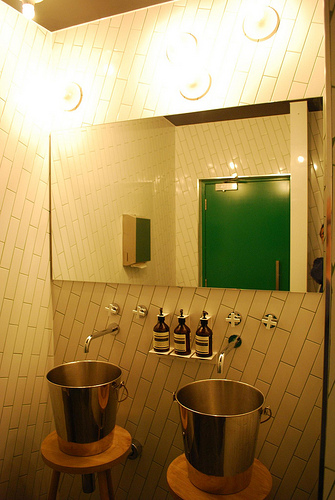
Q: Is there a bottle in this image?
A: Yes, there is a bottle.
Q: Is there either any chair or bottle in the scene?
A: Yes, there is a bottle.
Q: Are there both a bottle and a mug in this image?
A: No, there is a bottle but no mugs.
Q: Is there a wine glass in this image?
A: No, there are no wine glasses.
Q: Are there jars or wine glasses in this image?
A: No, there are no wine glasses or jars.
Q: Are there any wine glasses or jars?
A: No, there are no wine glasses or jars.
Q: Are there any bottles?
A: Yes, there is a bottle.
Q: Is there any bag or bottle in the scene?
A: Yes, there is a bottle.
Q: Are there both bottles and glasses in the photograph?
A: No, there is a bottle but no glasses.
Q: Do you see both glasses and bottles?
A: No, there is a bottle but no glasses.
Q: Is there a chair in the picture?
A: No, there are no chairs.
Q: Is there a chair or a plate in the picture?
A: No, there are no chairs or plates.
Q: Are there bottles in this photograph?
A: Yes, there is a bottle.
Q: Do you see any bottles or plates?
A: Yes, there is a bottle.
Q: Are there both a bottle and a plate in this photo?
A: No, there is a bottle but no plates.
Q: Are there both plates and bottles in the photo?
A: No, there is a bottle but no plates.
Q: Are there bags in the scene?
A: No, there are no bags.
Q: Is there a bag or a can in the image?
A: No, there are no bags or cans.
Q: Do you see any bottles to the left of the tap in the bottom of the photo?
A: Yes, there is a bottle to the left of the faucet.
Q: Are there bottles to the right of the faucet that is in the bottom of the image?
A: No, the bottle is to the left of the tap.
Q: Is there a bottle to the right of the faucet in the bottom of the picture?
A: No, the bottle is to the left of the tap.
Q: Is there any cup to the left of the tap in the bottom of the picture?
A: No, there is a bottle to the left of the tap.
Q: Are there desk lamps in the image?
A: No, there are no desk lamps.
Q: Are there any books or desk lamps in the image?
A: No, there are no desk lamps or books.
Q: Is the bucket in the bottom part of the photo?
A: Yes, the bucket is in the bottom of the image.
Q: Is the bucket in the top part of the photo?
A: No, the bucket is in the bottom of the image.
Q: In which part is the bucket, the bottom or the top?
A: The bucket is in the bottom of the image.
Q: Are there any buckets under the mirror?
A: Yes, there is a bucket under the mirror.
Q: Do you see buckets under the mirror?
A: Yes, there is a bucket under the mirror.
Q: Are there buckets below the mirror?
A: Yes, there is a bucket below the mirror.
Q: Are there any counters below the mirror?
A: No, there is a bucket below the mirror.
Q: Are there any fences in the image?
A: No, there are no fences.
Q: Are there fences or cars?
A: No, there are no fences or cars.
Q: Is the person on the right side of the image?
A: Yes, the person is on the right of the image.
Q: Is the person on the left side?
A: No, the person is on the right of the image.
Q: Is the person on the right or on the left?
A: The person is on the right of the image.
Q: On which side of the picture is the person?
A: The person is on the right of the image.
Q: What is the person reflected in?
A: The person is reflected in the mirror.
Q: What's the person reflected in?
A: The person is reflected in the mirror.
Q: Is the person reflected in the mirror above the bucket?
A: Yes, the person is reflected in the mirror.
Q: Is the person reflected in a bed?
A: No, the person is reflected in the mirror.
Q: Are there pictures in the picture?
A: No, there are no pictures.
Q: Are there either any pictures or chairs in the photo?
A: No, there are no pictures or chairs.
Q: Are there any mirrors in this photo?
A: Yes, there is a mirror.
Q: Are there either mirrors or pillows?
A: Yes, there is a mirror.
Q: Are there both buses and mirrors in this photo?
A: No, there is a mirror but no buses.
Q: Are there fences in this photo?
A: No, there are no fences.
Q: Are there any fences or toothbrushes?
A: No, there are no fences or toothbrushes.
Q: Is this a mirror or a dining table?
A: This is a mirror.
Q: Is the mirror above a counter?
A: No, the mirror is above the bucket.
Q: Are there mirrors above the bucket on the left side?
A: Yes, there is a mirror above the bucket.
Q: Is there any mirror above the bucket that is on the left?
A: Yes, there is a mirror above the bucket.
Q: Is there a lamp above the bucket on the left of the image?
A: No, there is a mirror above the bucket.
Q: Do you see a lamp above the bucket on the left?
A: No, there is a mirror above the bucket.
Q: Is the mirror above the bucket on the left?
A: Yes, the mirror is above the bucket.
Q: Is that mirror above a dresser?
A: No, the mirror is above the bucket.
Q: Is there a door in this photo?
A: Yes, there is a door.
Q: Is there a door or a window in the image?
A: Yes, there is a door.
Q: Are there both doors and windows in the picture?
A: No, there is a door but no windows.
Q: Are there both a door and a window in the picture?
A: No, there is a door but no windows.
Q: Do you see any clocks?
A: No, there are no clocks.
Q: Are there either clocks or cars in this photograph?
A: No, there are no clocks or cars.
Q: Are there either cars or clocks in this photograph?
A: No, there are no clocks or cars.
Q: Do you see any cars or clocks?
A: No, there are no clocks or cars.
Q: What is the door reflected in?
A: The door is reflected in the mirror.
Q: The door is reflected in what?
A: The door is reflected in the mirror.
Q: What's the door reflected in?
A: The door is reflected in the mirror.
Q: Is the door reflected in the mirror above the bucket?
A: Yes, the door is reflected in the mirror.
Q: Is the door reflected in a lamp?
A: No, the door is reflected in the mirror.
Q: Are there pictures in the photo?
A: No, there are no pictures.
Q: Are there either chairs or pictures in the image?
A: No, there are no pictures or chairs.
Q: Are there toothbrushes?
A: No, there are no toothbrushes.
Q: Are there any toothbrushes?
A: No, there are no toothbrushes.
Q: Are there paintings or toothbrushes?
A: No, there are no toothbrushes or paintings.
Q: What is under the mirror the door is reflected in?
A: The bucket is under the mirror.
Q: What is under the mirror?
A: The bucket is under the mirror.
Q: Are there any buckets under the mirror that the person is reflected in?
A: Yes, there is a bucket under the mirror.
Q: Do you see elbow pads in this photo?
A: No, there are no elbow pads.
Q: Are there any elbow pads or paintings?
A: No, there are no elbow pads or paintings.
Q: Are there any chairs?
A: No, there are no chairs.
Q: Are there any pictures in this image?
A: No, there are no pictures.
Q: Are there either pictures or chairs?
A: No, there are no pictures or chairs.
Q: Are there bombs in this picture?
A: No, there are no bombs.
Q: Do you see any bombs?
A: No, there are no bombs.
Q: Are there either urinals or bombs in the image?
A: No, there are no bombs or urinals.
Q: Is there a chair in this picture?
A: No, there are no chairs.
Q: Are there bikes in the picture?
A: No, there are no bikes.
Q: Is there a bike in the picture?
A: No, there are no bikes.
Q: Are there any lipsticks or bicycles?
A: No, there are no bicycles or lipsticks.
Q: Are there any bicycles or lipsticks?
A: No, there are no bicycles or lipsticks.